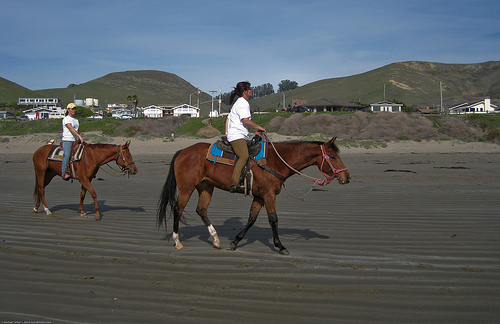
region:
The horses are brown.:
[7, 36, 419, 259]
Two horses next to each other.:
[20, 105, 375, 270]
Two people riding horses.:
[23, 56, 436, 281]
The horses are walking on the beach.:
[10, 123, 480, 321]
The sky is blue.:
[82, 5, 342, 46]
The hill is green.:
[302, 30, 497, 110]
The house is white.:
[440, 90, 497, 118]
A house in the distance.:
[138, 95, 199, 131]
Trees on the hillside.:
[245, 68, 300, 103]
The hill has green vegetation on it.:
[43, 59, 205, 111]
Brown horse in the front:
[145, 133, 356, 254]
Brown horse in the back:
[16, 136, 142, 221]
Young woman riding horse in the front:
[221, 75, 266, 191]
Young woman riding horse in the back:
[50, 95, 90, 180]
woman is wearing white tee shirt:
[220, 95, 256, 141]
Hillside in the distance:
[2, 55, 489, 101]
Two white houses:
[137, 95, 200, 120]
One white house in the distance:
[443, 86, 495, 121]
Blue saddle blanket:
[210, 131, 266, 158]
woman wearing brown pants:
[228, 138, 252, 184]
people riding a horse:
[10, 39, 421, 291]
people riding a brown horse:
[26, 66, 371, 308]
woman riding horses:
[44, 39, 418, 274]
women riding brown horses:
[25, 32, 367, 291]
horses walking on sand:
[22, 55, 434, 313]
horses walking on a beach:
[18, 61, 432, 323]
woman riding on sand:
[36, 63, 429, 310]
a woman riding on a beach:
[15, 17, 375, 323]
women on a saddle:
[27, 71, 352, 313]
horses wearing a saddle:
[21, 47, 376, 299]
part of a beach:
[196, 264, 241, 306]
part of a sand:
[336, 240, 398, 318]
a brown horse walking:
[157, 136, 354, 255]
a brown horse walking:
[30, 142, 137, 221]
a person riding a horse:
[30, 100, 140, 220]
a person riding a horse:
[159, 79, 352, 254]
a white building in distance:
[168, 102, 198, 118]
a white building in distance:
[139, 102, 161, 116]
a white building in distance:
[369, 98, 404, 113]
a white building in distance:
[447, 97, 494, 112]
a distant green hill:
[35, 69, 212, 104]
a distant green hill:
[224, 61, 499, 108]